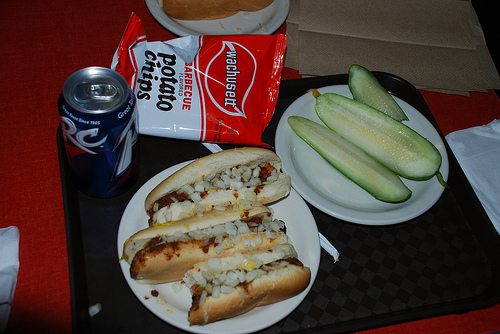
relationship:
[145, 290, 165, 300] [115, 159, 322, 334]
chili on plate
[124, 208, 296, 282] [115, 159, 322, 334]
chili dog on plate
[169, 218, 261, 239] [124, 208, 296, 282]
onion on chili dog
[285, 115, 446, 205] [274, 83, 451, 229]
pickle on plate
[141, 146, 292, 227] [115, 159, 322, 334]
hot dog on plate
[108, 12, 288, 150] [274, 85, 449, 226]
bag on plate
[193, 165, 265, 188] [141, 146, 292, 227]
onion on hot dog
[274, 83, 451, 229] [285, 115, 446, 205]
plate has a pickle